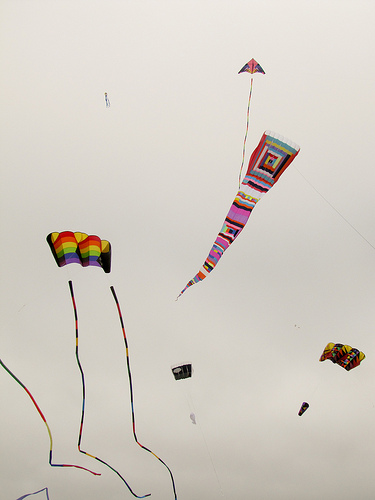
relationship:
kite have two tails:
[44, 229, 118, 274] [66, 282, 183, 500]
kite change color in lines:
[177, 135, 298, 293] [190, 188, 255, 287]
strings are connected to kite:
[238, 70, 255, 193] [177, 135, 298, 293]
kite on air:
[177, 135, 298, 293] [6, 4, 366, 498]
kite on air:
[322, 341, 372, 374] [6, 4, 366, 498]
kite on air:
[44, 229, 118, 274] [6, 4, 366, 498]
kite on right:
[322, 341, 372, 374] [310, 296, 373, 391]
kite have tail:
[177, 135, 298, 293] [183, 194, 260, 307]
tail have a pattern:
[183, 194, 260, 307] [167, 198, 251, 296]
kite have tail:
[44, 229, 118, 274] [109, 287, 181, 499]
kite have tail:
[44, 229, 118, 274] [67, 279, 154, 499]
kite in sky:
[44, 229, 118, 274] [6, 4, 366, 498]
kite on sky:
[322, 341, 372, 374] [6, 4, 366, 498]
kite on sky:
[177, 135, 298, 293] [6, 4, 366, 498]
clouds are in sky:
[6, 1, 349, 498] [6, 4, 366, 498]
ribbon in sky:
[0, 345, 99, 483] [6, 4, 366, 498]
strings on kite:
[238, 70, 255, 193] [177, 135, 298, 293]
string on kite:
[238, 70, 255, 193] [177, 135, 298, 293]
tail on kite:
[183, 194, 260, 307] [177, 135, 298, 293]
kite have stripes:
[44, 229, 118, 274] [43, 238, 113, 271]